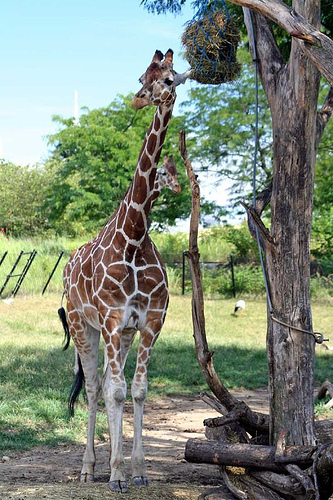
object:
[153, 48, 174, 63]
antlers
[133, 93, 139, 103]
nose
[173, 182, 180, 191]
nose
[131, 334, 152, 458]
left leg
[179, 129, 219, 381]
branches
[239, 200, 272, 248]
branches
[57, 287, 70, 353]
tail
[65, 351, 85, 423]
tail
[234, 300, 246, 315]
bird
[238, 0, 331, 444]
tree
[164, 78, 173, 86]
eye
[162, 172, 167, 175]
eye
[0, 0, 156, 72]
sky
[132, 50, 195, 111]
head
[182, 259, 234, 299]
gate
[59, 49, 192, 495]
giraffe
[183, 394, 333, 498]
chopped wood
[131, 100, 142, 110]
mouth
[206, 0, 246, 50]
leaves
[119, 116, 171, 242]
neck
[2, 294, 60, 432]
grass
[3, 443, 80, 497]
dirty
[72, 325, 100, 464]
leg griaffe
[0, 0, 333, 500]
zoo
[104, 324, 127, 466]
leg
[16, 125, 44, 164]
clouds